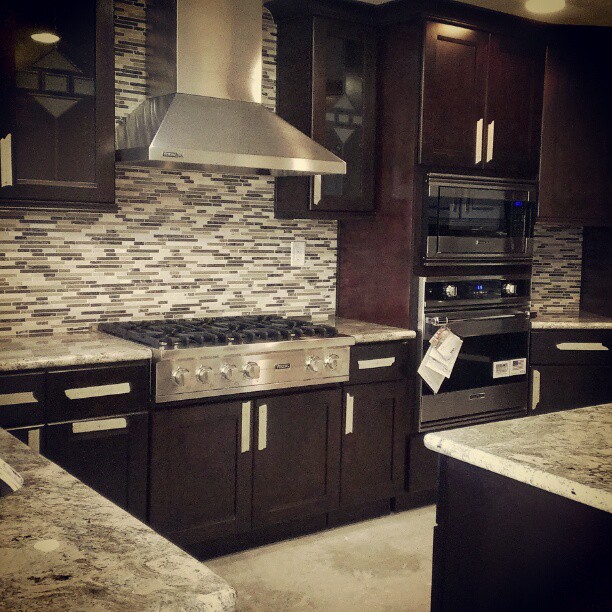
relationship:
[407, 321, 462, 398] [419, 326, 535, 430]
discloths hanging in oven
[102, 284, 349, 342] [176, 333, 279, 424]
burners on a stove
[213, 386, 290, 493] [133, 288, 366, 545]
cabinet door in a kitchen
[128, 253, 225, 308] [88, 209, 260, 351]
skinny tiles for a backsplash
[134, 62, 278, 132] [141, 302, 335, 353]
vent hood over a cooktop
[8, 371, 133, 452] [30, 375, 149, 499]
tape on door and drawers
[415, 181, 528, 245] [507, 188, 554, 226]
built-in microwave oven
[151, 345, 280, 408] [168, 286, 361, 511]
knobs on a cooktop stove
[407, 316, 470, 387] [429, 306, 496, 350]
papers hanging on an oven door